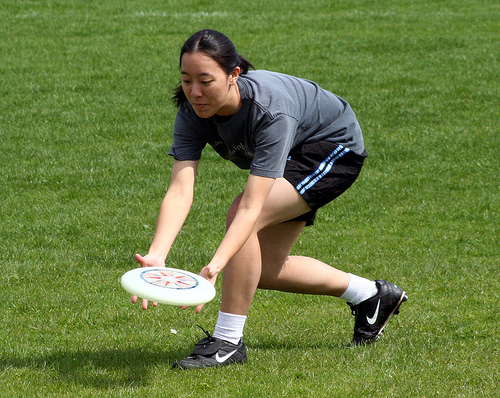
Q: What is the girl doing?
A: Catching the frisbee.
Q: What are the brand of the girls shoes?
A: Nike.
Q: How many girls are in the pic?
A: 1.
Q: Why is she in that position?
A: To catch the frisbee.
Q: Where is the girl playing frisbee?
A: On the field.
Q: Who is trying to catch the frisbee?
A: A girl.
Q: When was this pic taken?
A: During the day.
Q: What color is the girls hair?
A: Black.